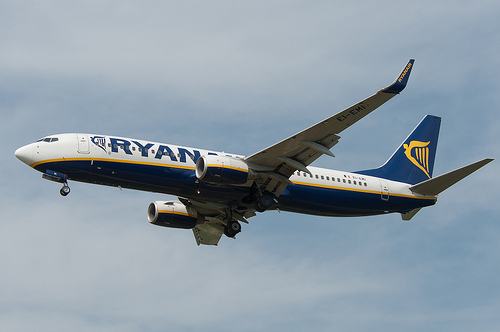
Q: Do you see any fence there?
A: No, there are no fences.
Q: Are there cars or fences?
A: No, there are no fences or cars.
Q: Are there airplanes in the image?
A: Yes, there is an airplane.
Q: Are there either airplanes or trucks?
A: Yes, there is an airplane.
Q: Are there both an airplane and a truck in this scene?
A: No, there is an airplane but no trucks.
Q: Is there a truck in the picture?
A: No, there are no trucks.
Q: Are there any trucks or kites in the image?
A: No, there are no trucks or kites.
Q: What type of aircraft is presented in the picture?
A: The aircraft is an airplane.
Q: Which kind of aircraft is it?
A: The aircraft is an airplane.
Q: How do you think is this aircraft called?
A: This is an airplane.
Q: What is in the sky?
A: The airplane is in the sky.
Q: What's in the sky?
A: The airplane is in the sky.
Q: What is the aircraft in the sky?
A: The aircraft is an airplane.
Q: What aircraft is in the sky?
A: The aircraft is an airplane.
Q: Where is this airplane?
A: The airplane is in the sky.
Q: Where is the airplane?
A: The airplane is in the sky.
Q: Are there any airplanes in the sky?
A: Yes, there is an airplane in the sky.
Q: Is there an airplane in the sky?
A: Yes, there is an airplane in the sky.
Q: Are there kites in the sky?
A: No, there is an airplane in the sky.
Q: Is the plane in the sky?
A: Yes, the plane is in the sky.